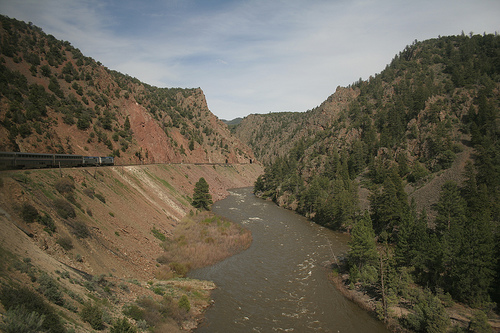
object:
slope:
[249, 40, 422, 203]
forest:
[269, 29, 499, 316]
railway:
[0, 160, 262, 173]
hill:
[256, 33, 500, 221]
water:
[252, 230, 328, 332]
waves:
[242, 216, 263, 224]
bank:
[3, 177, 217, 333]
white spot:
[107, 165, 187, 222]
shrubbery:
[189, 175, 216, 212]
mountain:
[0, 13, 258, 161]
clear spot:
[122, 100, 177, 165]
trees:
[0, 16, 121, 144]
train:
[0, 149, 116, 171]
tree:
[186, 175, 218, 213]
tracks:
[0, 158, 259, 173]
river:
[213, 186, 348, 312]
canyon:
[0, 0, 499, 333]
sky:
[41, 1, 500, 88]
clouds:
[0, 2, 499, 84]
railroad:
[0, 150, 117, 171]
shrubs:
[340, 236, 421, 312]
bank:
[173, 204, 254, 266]